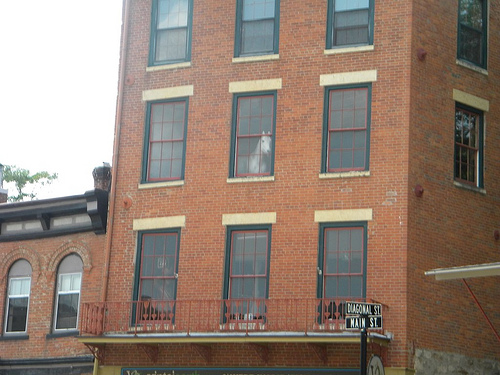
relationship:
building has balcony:
[94, 1, 499, 374] [80, 301, 389, 346]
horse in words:
[239, 131, 272, 173] [347, 303, 383, 329]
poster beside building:
[414, 353, 499, 375] [94, 1, 499, 374]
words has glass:
[347, 303, 383, 329] [236, 98, 272, 174]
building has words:
[94, 1, 499, 374] [347, 303, 383, 329]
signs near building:
[347, 303, 383, 329] [94, 1, 499, 374]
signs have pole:
[347, 303, 383, 329] [361, 329, 366, 374]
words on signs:
[347, 303, 383, 329] [347, 303, 383, 329]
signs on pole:
[347, 303, 383, 329] [361, 329, 366, 374]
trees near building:
[1, 164, 58, 201] [94, 1, 499, 374]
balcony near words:
[80, 301, 389, 346] [347, 303, 383, 329]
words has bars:
[347, 303, 383, 329] [238, 99, 270, 176]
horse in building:
[239, 131, 272, 173] [94, 1, 499, 374]